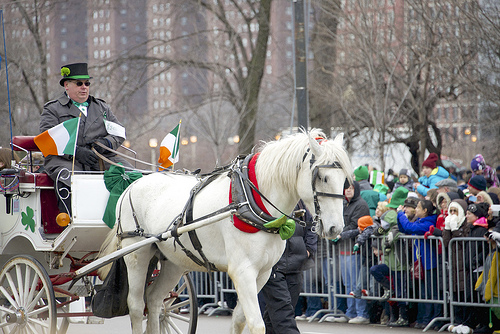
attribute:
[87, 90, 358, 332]
horse — White 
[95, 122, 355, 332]
white horse — white 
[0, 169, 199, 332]
white carriage — white 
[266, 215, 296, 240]
bow — green 